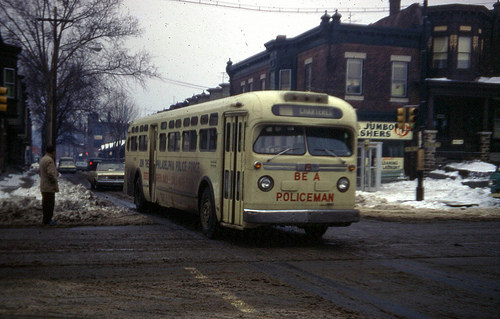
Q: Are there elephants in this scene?
A: No, there are no elephants.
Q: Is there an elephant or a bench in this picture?
A: No, there are no elephants or benches.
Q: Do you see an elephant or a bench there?
A: No, there are no elephants or benches.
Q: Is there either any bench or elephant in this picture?
A: No, there are no elephants or benches.